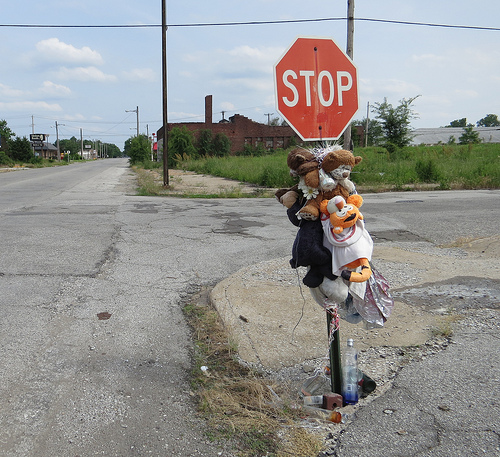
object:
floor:
[358, 188, 500, 240]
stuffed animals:
[274, 148, 321, 206]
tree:
[363, 94, 424, 162]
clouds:
[0, 99, 66, 115]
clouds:
[0, 79, 78, 100]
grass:
[181, 302, 325, 457]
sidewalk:
[210, 233, 499, 457]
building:
[383, 125, 500, 146]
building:
[156, 94, 373, 162]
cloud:
[39, 64, 115, 83]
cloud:
[185, 39, 290, 74]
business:
[28, 133, 59, 160]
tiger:
[318, 193, 373, 283]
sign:
[272, 36, 360, 141]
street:
[0, 155, 500, 454]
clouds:
[45, 112, 105, 123]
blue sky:
[0, 0, 499, 152]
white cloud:
[404, 87, 482, 107]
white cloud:
[356, 76, 420, 96]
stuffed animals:
[299, 149, 362, 222]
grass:
[170, 142, 500, 190]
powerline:
[0, 16, 500, 31]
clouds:
[118, 63, 160, 84]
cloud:
[14, 35, 105, 65]